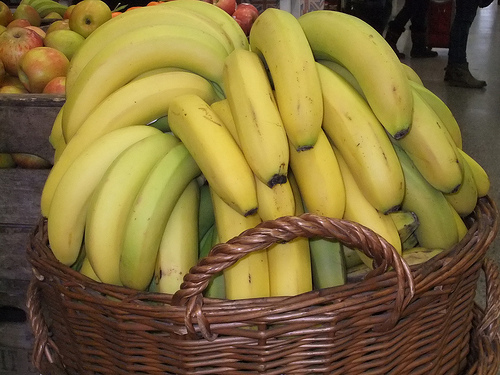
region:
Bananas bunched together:
[46, 1, 483, 296]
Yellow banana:
[166, 102, 264, 214]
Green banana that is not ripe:
[130, 134, 196, 290]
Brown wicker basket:
[21, 212, 491, 373]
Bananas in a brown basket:
[33, 5, 478, 374]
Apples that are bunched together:
[0, 21, 75, 96]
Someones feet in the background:
[409, 32, 491, 99]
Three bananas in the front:
[166, 13, 332, 206]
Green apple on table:
[48, 27, 83, 57]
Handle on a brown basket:
[164, 209, 421, 329]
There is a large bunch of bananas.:
[45, 5, 491, 300]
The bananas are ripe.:
[33, 0, 494, 301]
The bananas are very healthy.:
[26, 0, 498, 309]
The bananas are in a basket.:
[20, 2, 497, 374]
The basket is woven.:
[27, 197, 499, 371]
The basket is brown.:
[24, 188, 497, 373]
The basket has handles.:
[18, 154, 498, 374]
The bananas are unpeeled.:
[28, 3, 493, 295]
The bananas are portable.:
[31, 0, 492, 299]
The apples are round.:
[0, 1, 105, 99]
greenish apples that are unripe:
[0, 1, 111, 98]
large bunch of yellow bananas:
[35, 0, 491, 308]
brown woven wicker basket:
[0, 195, 496, 371]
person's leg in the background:
[432, 0, 487, 91]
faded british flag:
[293, 0, 324, 15]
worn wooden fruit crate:
[0, 92, 66, 372]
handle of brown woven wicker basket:
[165, 200, 415, 331]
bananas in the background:
[16, 0, 71, 20]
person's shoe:
[436, 56, 486, 91]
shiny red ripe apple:
[227, 2, 259, 30]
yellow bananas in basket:
[100, 13, 440, 209]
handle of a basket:
[258, 202, 373, 275]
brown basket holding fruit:
[129, 211, 351, 374]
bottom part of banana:
[287, 106, 328, 173]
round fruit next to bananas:
[0, 14, 92, 95]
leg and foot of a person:
[434, 20, 488, 115]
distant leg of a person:
[406, 16, 445, 62]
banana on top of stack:
[258, 12, 321, 119]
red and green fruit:
[16, 45, 73, 95]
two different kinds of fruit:
[6, 8, 184, 90]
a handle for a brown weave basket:
[161, 213, 441, 318]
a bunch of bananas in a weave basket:
[40, 5, 488, 278]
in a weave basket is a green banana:
[296, 237, 400, 289]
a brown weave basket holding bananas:
[26, 197, 498, 372]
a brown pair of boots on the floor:
[439, 47, 490, 102]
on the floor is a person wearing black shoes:
[383, 20, 443, 57]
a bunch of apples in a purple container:
[1, 0, 262, 158]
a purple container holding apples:
[1, 6, 97, 286]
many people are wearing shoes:
[321, 0, 486, 97]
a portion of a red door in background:
[408, 3, 495, 139]